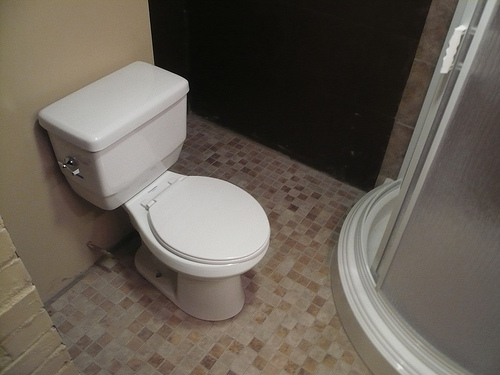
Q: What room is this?
A: A bathroom.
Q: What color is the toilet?
A: White.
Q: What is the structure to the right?
A: A shower.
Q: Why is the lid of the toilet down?
A: It isn't in use.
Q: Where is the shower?
A: To the right of the toilet.